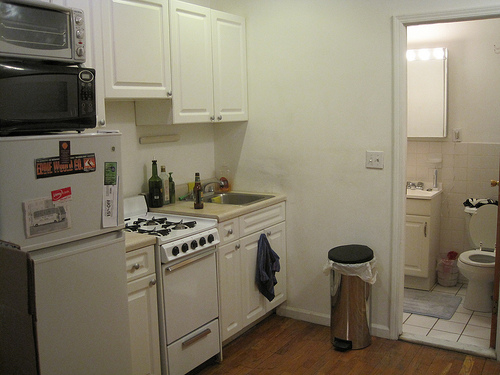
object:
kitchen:
[1, 0, 395, 374]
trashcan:
[327, 244, 375, 352]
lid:
[326, 244, 374, 265]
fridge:
[1, 134, 129, 375]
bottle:
[193, 172, 204, 210]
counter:
[150, 191, 283, 218]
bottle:
[149, 159, 163, 206]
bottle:
[160, 164, 171, 207]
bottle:
[168, 171, 176, 204]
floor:
[402, 281, 495, 358]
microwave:
[1, 63, 97, 136]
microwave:
[1, 0, 89, 64]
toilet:
[458, 203, 499, 313]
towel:
[256, 234, 281, 302]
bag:
[324, 259, 379, 285]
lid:
[469, 203, 500, 250]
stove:
[121, 212, 221, 258]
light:
[404, 48, 418, 63]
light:
[418, 47, 432, 61]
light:
[432, 47, 445, 60]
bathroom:
[406, 20, 499, 347]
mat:
[402, 289, 462, 320]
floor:
[238, 337, 498, 374]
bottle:
[216, 165, 231, 193]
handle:
[423, 221, 429, 238]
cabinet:
[407, 188, 443, 293]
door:
[489, 159, 499, 350]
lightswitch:
[365, 149, 385, 169]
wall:
[250, 0, 401, 332]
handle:
[167, 88, 174, 97]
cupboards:
[102, 0, 171, 100]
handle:
[209, 113, 216, 121]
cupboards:
[214, 8, 252, 122]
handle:
[216, 115, 224, 121]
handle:
[167, 248, 216, 272]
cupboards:
[126, 273, 161, 374]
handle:
[235, 241, 243, 250]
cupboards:
[216, 236, 247, 342]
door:
[214, 10, 248, 122]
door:
[268, 227, 292, 312]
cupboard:
[242, 221, 288, 319]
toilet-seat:
[457, 248, 499, 268]